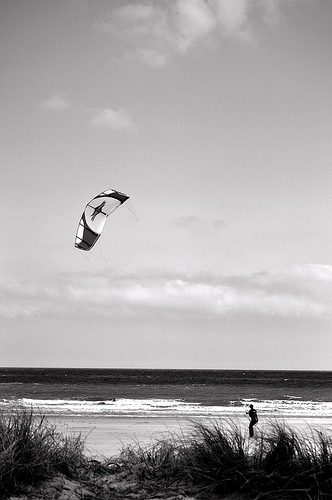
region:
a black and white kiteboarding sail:
[72, 187, 129, 256]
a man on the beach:
[246, 403, 258, 436]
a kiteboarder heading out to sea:
[72, 186, 257, 437]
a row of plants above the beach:
[0, 411, 331, 497]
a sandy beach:
[3, 405, 331, 448]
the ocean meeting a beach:
[1, 368, 331, 415]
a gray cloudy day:
[2, 0, 330, 370]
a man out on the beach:
[215, 402, 259, 437]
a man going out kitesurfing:
[72, 187, 260, 434]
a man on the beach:
[231, 404, 260, 433]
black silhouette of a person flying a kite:
[244, 401, 261, 439]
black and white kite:
[68, 184, 129, 254]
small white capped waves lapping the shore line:
[0, 391, 331, 418]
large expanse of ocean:
[1, 362, 330, 417]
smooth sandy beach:
[3, 408, 330, 458]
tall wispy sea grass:
[0, 399, 331, 497]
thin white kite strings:
[77, 196, 248, 416]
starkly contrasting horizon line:
[0, 360, 331, 380]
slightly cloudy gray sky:
[0, 0, 331, 373]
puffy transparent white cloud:
[91, 0, 285, 77]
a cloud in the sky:
[144, 7, 226, 58]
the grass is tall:
[157, 422, 249, 481]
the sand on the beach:
[100, 417, 145, 436]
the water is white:
[122, 400, 153, 409]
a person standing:
[242, 401, 266, 435]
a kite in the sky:
[64, 186, 136, 261]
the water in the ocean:
[144, 371, 227, 391]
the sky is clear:
[236, 214, 309, 252]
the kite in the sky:
[64, 176, 129, 261]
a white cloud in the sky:
[133, 280, 220, 311]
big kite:
[71, 176, 128, 262]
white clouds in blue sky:
[45, 63, 73, 99]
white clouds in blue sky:
[211, 201, 244, 226]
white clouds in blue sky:
[227, 280, 260, 320]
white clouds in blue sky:
[132, 336, 167, 370]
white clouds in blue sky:
[49, 302, 85, 328]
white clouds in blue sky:
[166, 58, 209, 94]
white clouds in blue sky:
[56, 78, 117, 114]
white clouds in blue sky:
[226, 168, 283, 206]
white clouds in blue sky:
[194, 274, 242, 320]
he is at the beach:
[66, 177, 282, 478]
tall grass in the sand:
[2, 408, 327, 498]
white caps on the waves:
[10, 392, 331, 418]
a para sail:
[45, 129, 285, 442]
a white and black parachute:
[57, 171, 219, 365]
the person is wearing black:
[239, 370, 271, 448]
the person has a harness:
[234, 392, 281, 453]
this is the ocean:
[2, 360, 328, 417]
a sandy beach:
[13, 414, 330, 459]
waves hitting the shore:
[2, 387, 331, 432]